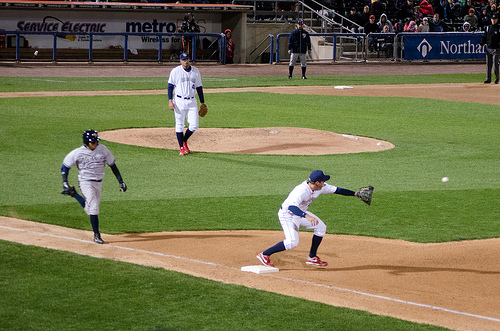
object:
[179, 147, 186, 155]
feet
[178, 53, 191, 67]
head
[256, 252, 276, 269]
foot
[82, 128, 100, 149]
head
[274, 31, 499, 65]
fence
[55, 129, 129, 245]
head man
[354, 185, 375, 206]
glove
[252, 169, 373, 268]
man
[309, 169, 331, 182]
hat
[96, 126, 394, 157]
pitcher's mound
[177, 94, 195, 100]
belt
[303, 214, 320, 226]
hand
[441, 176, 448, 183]
ball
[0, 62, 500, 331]
field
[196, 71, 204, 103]
arm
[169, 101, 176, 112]
hand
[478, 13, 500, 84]
umpire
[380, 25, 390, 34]
fans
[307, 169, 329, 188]
head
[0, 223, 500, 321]
base line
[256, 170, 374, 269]
baseball player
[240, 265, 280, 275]
base